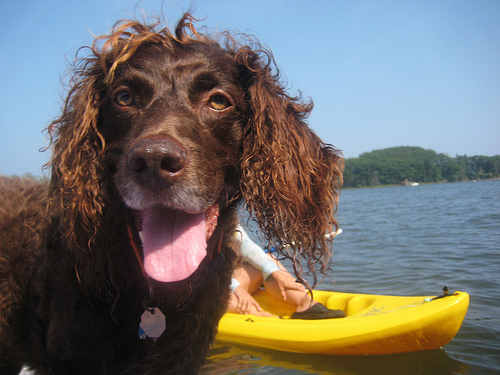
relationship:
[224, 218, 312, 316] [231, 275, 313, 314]
woman/legs grabbing legs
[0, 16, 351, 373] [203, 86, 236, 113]
dog has eye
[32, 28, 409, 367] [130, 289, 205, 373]
dog wearing tag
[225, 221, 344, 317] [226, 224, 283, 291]
person wearing shirt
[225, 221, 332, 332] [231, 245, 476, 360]
person sitting in boat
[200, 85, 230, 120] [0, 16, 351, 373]
eye of dog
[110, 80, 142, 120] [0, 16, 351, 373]
eye of dog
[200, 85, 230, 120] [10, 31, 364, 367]
eye of dog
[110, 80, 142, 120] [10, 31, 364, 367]
eye of dog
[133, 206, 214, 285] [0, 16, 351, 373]
tongue of dog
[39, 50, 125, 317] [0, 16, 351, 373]
ear of dog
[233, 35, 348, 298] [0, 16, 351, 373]
ear of dog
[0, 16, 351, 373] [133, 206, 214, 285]
dog sticking out tongue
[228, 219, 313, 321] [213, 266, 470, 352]
woman sitting in boat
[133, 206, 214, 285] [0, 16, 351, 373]
tongue sticking out of dog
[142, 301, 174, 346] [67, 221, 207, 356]
tag attached to collar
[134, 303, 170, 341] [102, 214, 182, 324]
symbol on chain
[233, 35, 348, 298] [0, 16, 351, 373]
ear on dog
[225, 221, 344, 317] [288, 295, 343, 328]
person wearing shoes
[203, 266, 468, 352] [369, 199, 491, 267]
boat in water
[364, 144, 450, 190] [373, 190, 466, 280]
trees behind water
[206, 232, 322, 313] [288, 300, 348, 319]
man wearing wear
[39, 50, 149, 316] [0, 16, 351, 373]
ear of dog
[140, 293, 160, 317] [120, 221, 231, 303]
loop on collar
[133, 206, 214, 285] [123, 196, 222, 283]
tongue in mouth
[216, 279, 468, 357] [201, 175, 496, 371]
kayak in water